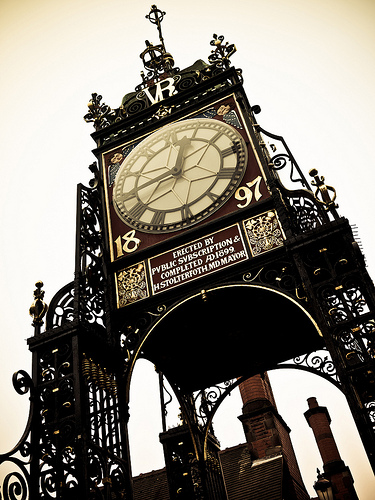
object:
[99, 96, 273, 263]
clock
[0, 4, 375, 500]
tower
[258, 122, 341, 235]
metal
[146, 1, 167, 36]
peak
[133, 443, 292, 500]
roof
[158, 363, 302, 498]
church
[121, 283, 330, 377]
arch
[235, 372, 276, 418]
steeple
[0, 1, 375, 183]
sky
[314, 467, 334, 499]
lamp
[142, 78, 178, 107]
initials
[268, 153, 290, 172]
scrolling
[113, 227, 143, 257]
numbers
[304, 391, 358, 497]
building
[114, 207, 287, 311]
plaque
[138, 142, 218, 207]
star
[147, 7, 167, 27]
spheres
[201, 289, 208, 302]
knob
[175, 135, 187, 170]
hand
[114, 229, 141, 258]
18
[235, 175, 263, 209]
97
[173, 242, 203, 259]
errected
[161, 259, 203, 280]
completed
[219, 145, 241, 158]
numerals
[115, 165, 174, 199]
hand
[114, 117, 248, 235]
face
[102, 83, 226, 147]
trim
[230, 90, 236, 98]
corner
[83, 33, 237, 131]
filigree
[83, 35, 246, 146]
parapets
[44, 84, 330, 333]
framing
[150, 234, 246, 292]
writing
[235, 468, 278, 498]
shingles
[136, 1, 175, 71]
design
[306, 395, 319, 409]
chimney